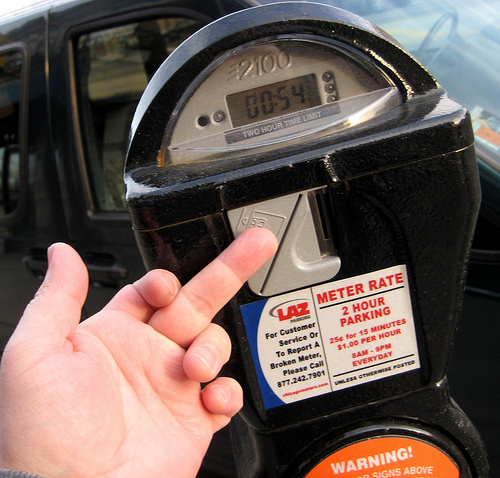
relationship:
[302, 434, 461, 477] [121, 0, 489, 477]
sticker attached to meter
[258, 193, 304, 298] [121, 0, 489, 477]
coin slot part of meter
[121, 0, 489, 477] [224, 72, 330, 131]
meter has time display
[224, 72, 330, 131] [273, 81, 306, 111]
time display shows 54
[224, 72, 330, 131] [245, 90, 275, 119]
time display showing zeroes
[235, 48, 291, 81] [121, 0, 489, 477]
number 2100 on meter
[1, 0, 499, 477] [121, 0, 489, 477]
vehicle behind meter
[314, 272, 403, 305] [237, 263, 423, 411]
meter rate on top of sticker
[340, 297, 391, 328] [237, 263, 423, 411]
2 hour parking on sticker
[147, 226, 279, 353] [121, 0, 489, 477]
middle finger aimed at meter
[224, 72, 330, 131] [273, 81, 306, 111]
time display showing 54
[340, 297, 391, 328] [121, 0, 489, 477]
2 hour parking on meter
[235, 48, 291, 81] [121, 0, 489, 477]
number 2100 on top of meter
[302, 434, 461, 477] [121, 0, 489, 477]
sticker stuck to meter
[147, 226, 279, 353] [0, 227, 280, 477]
middle finger part of hand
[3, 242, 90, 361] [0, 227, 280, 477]
thumb part of hand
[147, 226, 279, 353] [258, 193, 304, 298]
middle finger pointing at coin slot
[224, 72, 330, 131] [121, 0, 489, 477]
time display on meter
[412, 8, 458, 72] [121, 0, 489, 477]
steering wheel behind meter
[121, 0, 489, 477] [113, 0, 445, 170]
meter has top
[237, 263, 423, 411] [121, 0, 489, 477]
sticker stuck to meter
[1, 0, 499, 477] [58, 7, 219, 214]
vehicle has window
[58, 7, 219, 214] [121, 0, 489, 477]
window behind meter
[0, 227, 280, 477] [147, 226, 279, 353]
hand has middle finger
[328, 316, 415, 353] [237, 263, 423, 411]
rates are on sticker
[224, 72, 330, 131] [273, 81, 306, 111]
time display displaying 54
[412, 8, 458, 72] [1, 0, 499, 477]
steering wheel inside of vehicle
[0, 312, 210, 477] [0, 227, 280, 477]
palm part of hand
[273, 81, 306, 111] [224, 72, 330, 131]
54 remaining on time display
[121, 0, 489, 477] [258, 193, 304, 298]
meter has coin slot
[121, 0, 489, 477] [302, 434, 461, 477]
meter has sticker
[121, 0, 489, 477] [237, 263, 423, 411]
meter has sticker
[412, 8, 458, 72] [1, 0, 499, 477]
steering wheel inside vehicle